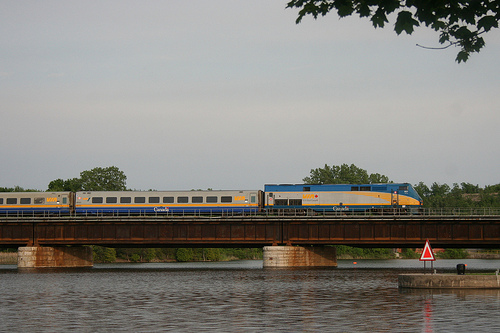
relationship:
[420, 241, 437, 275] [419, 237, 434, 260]
sign displays a warning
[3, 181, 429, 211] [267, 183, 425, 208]
train has lead car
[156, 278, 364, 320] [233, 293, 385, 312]
water has ripples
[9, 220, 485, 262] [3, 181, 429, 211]
bridge passed over by train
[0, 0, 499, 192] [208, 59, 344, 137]
sky a bit dark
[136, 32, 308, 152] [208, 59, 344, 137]
sky kind of dark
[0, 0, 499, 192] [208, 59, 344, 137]
sky somewhat dark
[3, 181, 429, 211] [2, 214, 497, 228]
train on tracks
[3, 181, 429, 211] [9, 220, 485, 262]
train on a bridge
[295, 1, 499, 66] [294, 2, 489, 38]
tree has leaves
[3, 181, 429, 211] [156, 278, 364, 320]
train next to water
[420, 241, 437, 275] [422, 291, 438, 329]
sign has reflection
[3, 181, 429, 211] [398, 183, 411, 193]
train has window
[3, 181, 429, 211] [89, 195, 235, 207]
train has a row of windows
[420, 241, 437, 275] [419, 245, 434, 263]
sign colored red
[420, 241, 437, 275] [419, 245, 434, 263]
sign color red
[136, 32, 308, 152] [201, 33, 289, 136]
sky has a part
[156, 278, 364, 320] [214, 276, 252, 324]
water has a part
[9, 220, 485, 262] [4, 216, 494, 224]
bridge has an edge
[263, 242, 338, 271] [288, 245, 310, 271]
stand has a part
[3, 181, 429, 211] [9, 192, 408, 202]
train has a side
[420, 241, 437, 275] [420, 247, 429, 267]
post has a part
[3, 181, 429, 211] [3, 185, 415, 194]
train has an edge